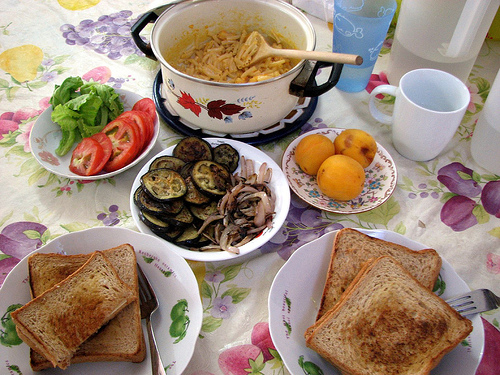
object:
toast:
[305, 253, 473, 374]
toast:
[12, 250, 137, 367]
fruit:
[317, 154, 365, 202]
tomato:
[68, 138, 107, 177]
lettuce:
[52, 76, 123, 158]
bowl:
[30, 87, 161, 180]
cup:
[368, 68, 471, 161]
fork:
[445, 288, 500, 316]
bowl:
[268, 228, 486, 374]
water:
[390, 38, 476, 106]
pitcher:
[387, 0, 500, 88]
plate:
[283, 128, 399, 214]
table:
[1, 1, 498, 374]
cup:
[332, 1, 396, 92]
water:
[335, 65, 372, 94]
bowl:
[1, 226, 204, 374]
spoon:
[238, 30, 364, 67]